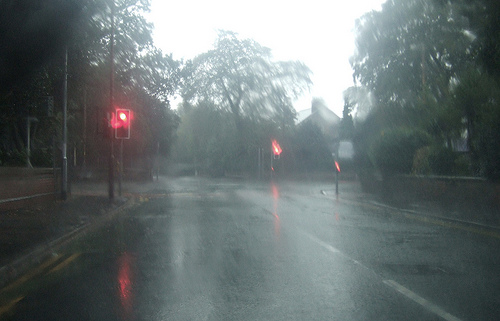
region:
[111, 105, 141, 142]
traffic light shining red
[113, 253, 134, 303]
red light shining on the ground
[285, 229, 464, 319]
white line painted on the ground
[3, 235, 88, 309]
yellow lines on the side of the road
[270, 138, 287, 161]
blurry red light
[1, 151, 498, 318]
no cars on the road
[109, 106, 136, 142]
top light on the traffic light is shining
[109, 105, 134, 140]
traffic light on a pole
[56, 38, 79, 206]
pole coming out of the sidewalk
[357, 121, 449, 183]
two green bushes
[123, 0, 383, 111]
light in daytime sky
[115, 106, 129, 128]
glowing red traffic light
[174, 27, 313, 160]
tree overlooking street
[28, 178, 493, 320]
wet pavement of street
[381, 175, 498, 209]
wall under bushes along sidewalk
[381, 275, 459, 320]
white line on road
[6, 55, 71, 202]
pole next to wall on sidewalk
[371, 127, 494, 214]
trimmed bushes behind wall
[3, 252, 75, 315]
double lines on street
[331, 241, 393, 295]
White line marking road.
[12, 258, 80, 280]
Yellow lines marking road.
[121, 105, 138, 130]
Red light illuminated on traffic signal.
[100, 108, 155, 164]
Traffic signal attached to pole.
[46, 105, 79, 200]
Large gray pole on sidewalk.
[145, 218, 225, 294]
Pavement is wet and shiny.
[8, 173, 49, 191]
Brick wall next to sidewalk.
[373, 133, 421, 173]
Green bushes near wall.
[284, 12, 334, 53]
Sky is white and bright.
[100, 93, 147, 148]
The street light is red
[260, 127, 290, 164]
The street light is red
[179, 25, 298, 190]
The tree is by the street light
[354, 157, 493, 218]
There are bushes on a barrier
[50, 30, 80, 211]
The pole is silver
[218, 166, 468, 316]
There is a white line in the center of the road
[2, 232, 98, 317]
There is a yellow line on the side of the road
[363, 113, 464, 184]
There is a bush on the side of the road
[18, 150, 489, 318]
The road is black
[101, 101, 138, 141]
light on the corner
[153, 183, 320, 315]
street slick from rain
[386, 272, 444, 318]
marking on the street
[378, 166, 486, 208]
stone wall around lawn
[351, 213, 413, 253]
lane in a street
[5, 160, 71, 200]
brick wall around lawn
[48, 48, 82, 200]
pole on the sidewalk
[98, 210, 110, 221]
curb on the sidewalk